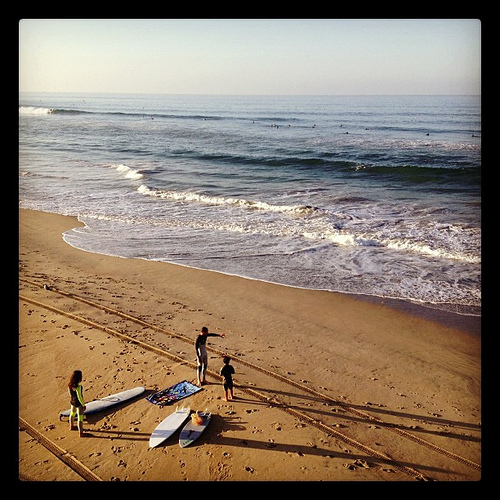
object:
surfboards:
[179, 409, 212, 448]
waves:
[18, 100, 483, 264]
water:
[18, 94, 480, 316]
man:
[194, 326, 226, 387]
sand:
[19, 244, 481, 481]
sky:
[19, 19, 479, 94]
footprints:
[19, 246, 477, 478]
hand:
[219, 332, 225, 338]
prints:
[255, 325, 296, 387]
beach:
[19, 207, 480, 480]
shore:
[19, 199, 481, 481]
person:
[68, 369, 87, 437]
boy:
[219, 356, 236, 402]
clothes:
[219, 365, 233, 391]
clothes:
[198, 342, 207, 359]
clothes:
[68, 383, 85, 408]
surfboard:
[148, 407, 191, 448]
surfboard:
[58, 386, 145, 423]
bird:
[43, 283, 48, 290]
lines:
[42, 276, 142, 351]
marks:
[32, 281, 454, 469]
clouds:
[273, 42, 343, 82]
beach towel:
[145, 379, 203, 407]